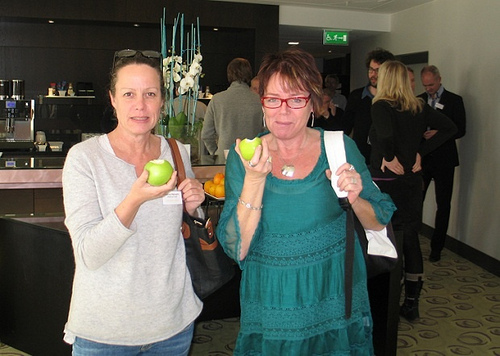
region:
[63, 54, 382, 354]
these are ladies eating apples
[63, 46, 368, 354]
the ladies are two in number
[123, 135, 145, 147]
the lady has a light skin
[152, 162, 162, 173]
this is an apple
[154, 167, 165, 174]
the apple is green in color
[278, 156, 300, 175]
this is a necklace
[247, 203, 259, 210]
this is a wrist band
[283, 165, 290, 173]
the necklace is shinny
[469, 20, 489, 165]
this is a wall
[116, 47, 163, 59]
this is a spectacle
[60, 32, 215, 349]
woman eating a apple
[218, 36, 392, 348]
woman holding a apple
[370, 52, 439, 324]
woman with hands on hips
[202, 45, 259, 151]
man wearing gray sweater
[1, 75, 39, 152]
coffee maker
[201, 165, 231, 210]
bowl with oranges in it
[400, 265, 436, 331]
black boots with gray socks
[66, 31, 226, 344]
woman holding brown purse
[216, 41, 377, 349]
woman wearing red glasses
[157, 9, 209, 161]
white flowers with blue sticks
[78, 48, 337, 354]
two women with apples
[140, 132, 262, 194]
two green apples with bites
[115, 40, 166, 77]
glasses on woman's head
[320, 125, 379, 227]
strap of bag on shoulder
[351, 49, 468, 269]
group of people standing in hall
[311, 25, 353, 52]
green sign on ceiling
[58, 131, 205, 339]
gray sweater on woman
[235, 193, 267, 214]
bracelet on woman's wrist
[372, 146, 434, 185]
two hands on back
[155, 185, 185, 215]
tag on woman's chest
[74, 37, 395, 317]
two women eating apples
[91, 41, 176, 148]
woman with glasses on her head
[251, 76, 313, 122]
woman wearing red framed glasses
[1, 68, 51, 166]
coffee maker on counter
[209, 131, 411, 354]
woman wearing turquoise dress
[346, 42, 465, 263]
group of people standing near entrance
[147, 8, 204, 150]
tall floral arrangement on counter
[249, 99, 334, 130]
woman wearing dangle earrings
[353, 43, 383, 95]
man with beard and mustache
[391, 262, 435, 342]
woman wearing black boots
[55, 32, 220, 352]
woman in white with apple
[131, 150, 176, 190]
green apple with bite missing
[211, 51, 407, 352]
a woman in green with apple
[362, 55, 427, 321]
woman in black suit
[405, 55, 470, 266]
older man in black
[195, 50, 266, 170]
man in a gray sweater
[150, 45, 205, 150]
pot of orchid flowers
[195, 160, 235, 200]
a basket of oranges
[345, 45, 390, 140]
man in black and blue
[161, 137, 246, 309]
black purse